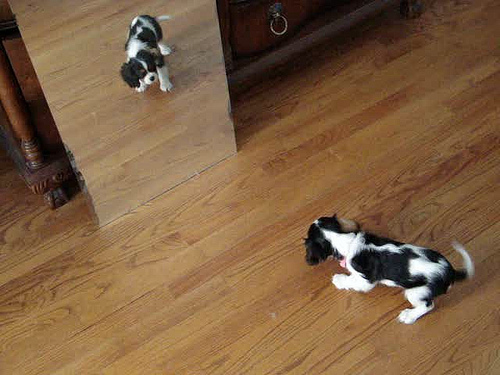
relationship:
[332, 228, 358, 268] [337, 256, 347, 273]
collar has orange tag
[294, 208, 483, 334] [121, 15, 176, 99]
puppy has reflection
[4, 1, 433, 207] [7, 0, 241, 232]
dresser behind mirror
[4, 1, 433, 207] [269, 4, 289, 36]
dresser has handle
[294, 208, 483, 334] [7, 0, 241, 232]
puppy looking at mirror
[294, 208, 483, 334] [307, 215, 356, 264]
puppy has floppy ears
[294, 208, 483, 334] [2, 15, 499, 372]
puppy standing on floor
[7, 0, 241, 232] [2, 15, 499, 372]
mirror on top of floor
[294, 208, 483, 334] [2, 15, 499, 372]
dog standing on floor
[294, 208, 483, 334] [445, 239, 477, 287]
puppy has a tail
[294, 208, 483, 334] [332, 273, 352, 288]
puppy has a paw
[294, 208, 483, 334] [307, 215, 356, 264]
puppy has a ear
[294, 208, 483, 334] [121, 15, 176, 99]
puppy has a reflection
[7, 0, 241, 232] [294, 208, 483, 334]
mirror in front of puppy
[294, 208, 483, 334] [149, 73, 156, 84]
puppy has a nose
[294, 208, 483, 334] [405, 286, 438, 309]
puppy has a thigh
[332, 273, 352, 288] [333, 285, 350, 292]
paw has an edge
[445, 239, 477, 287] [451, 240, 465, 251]
tail has a tip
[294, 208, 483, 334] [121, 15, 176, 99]
puppy looking at h reflection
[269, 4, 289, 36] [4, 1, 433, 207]
pull on dresser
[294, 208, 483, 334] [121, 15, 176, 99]
dog looking at h reflection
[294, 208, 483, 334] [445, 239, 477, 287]
puppy wagging its tail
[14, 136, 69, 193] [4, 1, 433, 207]
decorations are on dresser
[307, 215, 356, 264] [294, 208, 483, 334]
black ears on puppy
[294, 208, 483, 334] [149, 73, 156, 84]
puppy has black nose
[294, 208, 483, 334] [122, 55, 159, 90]
puppy has white patch on face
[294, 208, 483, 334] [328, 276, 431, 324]
puppy has white paws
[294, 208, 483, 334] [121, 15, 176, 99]
puppy looking at its reflection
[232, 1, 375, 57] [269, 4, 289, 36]
dresser drawer has a handle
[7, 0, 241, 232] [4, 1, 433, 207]
mirror leaning on dresser